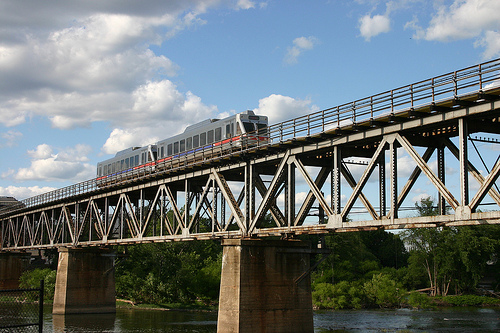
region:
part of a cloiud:
[161, 95, 196, 102]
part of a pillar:
[242, 303, 264, 331]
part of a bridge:
[261, 208, 289, 240]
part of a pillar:
[238, 245, 254, 273]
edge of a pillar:
[231, 288, 247, 308]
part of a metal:
[248, 164, 277, 212]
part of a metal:
[245, 210, 260, 232]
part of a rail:
[313, 110, 322, 125]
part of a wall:
[261, 288, 270, 304]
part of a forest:
[368, 268, 376, 277]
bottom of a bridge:
[396, 155, 422, 198]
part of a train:
[253, 110, 262, 123]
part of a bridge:
[326, 127, 334, 141]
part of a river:
[346, 319, 350, 329]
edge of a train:
[243, 116, 246, 135]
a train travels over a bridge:
[22, 53, 477, 258]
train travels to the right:
[10, 64, 490, 297]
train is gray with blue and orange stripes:
[71, 100, 274, 188]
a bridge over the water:
[9, 58, 499, 329]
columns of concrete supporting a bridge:
[31, 173, 356, 331]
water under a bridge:
[3, 213, 495, 332]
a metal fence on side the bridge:
[281, 49, 497, 133]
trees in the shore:
[10, 208, 480, 331]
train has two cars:
[78, 92, 283, 192]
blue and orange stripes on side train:
[78, 133, 242, 185]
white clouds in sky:
[208, 1, 496, 58]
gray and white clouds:
[1, 0, 199, 119]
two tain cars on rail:
[95, 112, 269, 200]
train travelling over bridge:
[47, 59, 497, 331]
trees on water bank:
[319, 229, 497, 331]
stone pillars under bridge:
[52, 235, 318, 331]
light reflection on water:
[314, 304, 495, 331]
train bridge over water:
[55, 107, 497, 332]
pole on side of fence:
[0, 278, 44, 331]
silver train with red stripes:
[95, 111, 269, 186]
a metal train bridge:
[7, 68, 497, 253]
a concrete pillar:
[46, 252, 113, 320]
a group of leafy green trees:
[312, 226, 495, 316]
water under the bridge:
[45, 303, 477, 330]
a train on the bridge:
[89, 116, 276, 186]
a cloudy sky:
[15, 0, 162, 139]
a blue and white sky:
[23, 1, 402, 81]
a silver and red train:
[97, 106, 271, 187]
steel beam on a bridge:
[65, 122, 496, 244]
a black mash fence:
[2, 278, 55, 332]